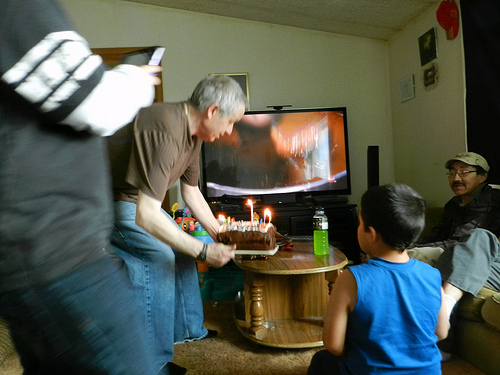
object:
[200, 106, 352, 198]
screen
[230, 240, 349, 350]
table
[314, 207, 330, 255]
bottle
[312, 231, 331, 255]
juice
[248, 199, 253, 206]
flames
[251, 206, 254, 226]
candle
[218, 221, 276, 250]
cake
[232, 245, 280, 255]
platter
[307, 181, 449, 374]
kid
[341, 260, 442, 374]
shirt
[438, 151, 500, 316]
man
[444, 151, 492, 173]
hat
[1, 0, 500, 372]
room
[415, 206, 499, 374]
sofa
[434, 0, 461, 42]
hat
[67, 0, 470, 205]
wall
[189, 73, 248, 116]
hair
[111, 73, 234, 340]
man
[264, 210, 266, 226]
candle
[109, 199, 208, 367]
jeans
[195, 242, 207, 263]
watch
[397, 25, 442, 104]
pictures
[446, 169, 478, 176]
glasses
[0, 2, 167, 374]
person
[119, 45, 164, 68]
phone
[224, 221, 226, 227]
candles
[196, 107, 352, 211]
tv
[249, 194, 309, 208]
stand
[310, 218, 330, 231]
labeling